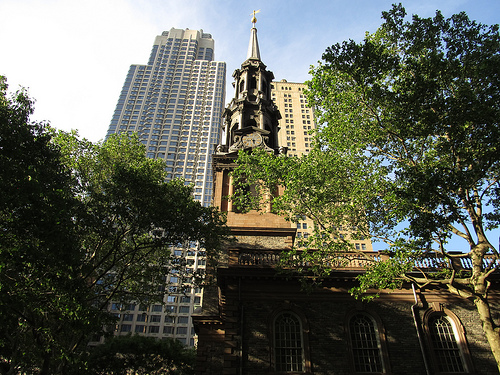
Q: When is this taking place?
A: Daytime.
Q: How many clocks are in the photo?
A: One.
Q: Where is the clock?
A: On the front of stone tower.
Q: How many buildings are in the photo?
A: Three.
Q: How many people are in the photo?
A: None.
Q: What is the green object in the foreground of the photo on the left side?
A: Trees.